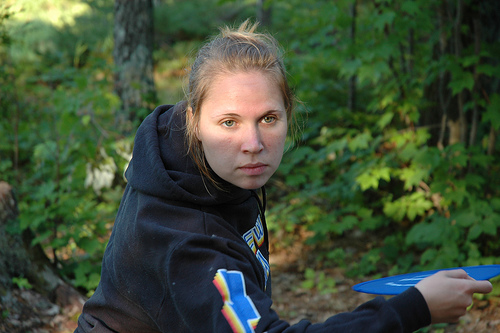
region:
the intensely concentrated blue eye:
[220, 118, 236, 128]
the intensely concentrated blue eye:
[263, 113, 275, 125]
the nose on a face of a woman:
[241, 118, 263, 155]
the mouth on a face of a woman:
[239, 164, 267, 172]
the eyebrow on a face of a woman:
[213, 110, 240, 119]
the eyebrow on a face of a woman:
[260, 108, 277, 115]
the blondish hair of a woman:
[184, 23, 297, 178]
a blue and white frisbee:
[354, 260, 499, 305]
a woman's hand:
[415, 266, 489, 316]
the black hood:
[126, 104, 227, 203]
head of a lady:
[223, 76, 248, 108]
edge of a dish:
[353, 272, 387, 299]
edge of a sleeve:
[401, 267, 426, 325]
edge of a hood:
[153, 170, 211, 235]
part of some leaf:
[410, 220, 447, 249]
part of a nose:
[243, 138, 260, 158]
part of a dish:
[410, 282, 425, 316]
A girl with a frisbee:
[60, 30, 475, 317]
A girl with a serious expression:
[107, 21, 327, 232]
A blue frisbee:
[335, 218, 493, 313]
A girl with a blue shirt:
[111, 14, 328, 322]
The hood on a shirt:
[93, 91, 213, 252]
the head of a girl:
[165, 21, 302, 209]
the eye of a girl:
[210, 100, 290, 133]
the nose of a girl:
[233, 126, 273, 159]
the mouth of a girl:
[222, 159, 279, 185]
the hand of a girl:
[396, 241, 475, 330]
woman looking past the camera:
[195, 23, 320, 185]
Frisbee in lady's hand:
[355, 235, 485, 315]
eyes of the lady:
[186, 95, 286, 151]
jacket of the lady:
[115, 185, 265, 305]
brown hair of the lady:
[165, 40, 255, 95]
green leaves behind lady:
[345, 125, 445, 205]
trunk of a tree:
[52, 15, 162, 106]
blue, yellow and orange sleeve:
[201, 255, 246, 330]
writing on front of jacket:
[231, 205, 271, 257]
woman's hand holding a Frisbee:
[425, 252, 485, 324]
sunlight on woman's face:
[156, 64, 316, 181]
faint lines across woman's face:
[226, 84, 281, 106]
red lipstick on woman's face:
[228, 150, 284, 180]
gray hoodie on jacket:
[115, 99, 193, 182]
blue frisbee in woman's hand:
[358, 237, 492, 314]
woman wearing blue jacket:
[88, 174, 282, 303]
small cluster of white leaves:
[76, 147, 124, 178]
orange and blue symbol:
[196, 265, 270, 322]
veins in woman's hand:
[441, 277, 479, 313]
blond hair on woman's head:
[171, 27, 286, 88]